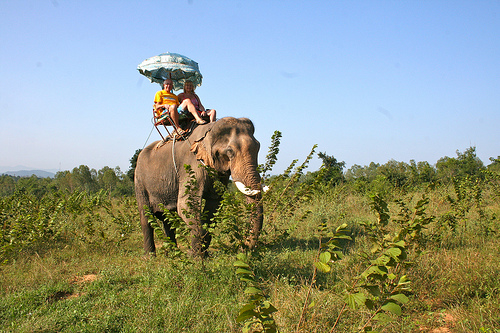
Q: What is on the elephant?
A: The couple.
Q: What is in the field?
A: Green plants.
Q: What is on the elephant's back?
A: The couple.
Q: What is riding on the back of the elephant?
A: The couple.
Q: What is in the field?
A: The elephant.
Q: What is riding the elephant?
A: Two people.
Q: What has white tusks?
A: The large grey elephant.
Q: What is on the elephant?
A: The people with an umbrella.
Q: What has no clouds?
A: The clear sky.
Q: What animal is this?
A: An elephant.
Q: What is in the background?
A: The sky.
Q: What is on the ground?
A: Large weeds.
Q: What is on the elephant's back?
A: People sitting on bench.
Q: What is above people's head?
A: An umbrella.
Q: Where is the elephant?
A: In an open field.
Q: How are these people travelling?
A: By elephant.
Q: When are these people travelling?
A: Day time.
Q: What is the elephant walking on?
A: Grass.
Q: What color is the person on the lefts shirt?
A: Yellow.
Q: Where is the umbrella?
A: Shading the people.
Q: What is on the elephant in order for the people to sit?
A: Chairs.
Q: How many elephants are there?
A: One.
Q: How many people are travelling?
A: Two.